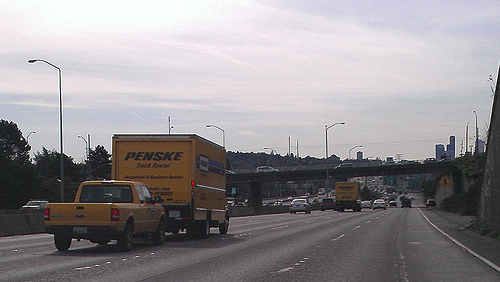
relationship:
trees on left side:
[0, 115, 326, 199] [1, 4, 342, 281]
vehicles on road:
[18, 131, 416, 254] [2, 181, 499, 281]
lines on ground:
[74, 207, 401, 279] [2, 181, 499, 281]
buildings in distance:
[349, 135, 487, 158] [227, 140, 491, 170]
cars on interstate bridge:
[224, 159, 353, 174] [222, 158, 458, 207]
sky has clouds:
[1, 8, 500, 165] [1, 0, 499, 162]